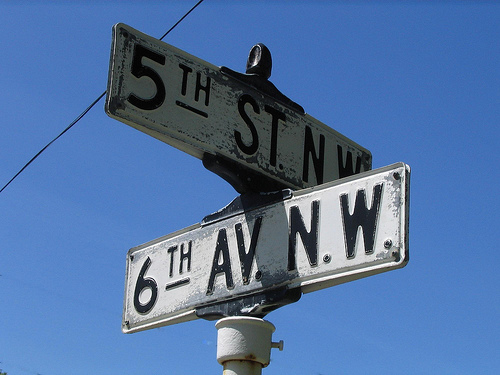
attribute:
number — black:
[128, 42, 166, 111]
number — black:
[133, 256, 157, 315]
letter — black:
[336, 182, 384, 260]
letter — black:
[284, 200, 321, 272]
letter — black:
[233, 215, 263, 285]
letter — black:
[205, 228, 236, 297]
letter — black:
[178, 240, 193, 275]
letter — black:
[166, 244, 177, 277]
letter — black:
[178, 62, 193, 96]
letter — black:
[194, 71, 211, 106]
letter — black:
[232, 92, 260, 155]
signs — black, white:
[105, 21, 411, 335]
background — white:
[103, 23, 372, 190]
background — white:
[122, 161, 410, 335]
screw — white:
[272, 340, 284, 352]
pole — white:
[214, 316, 276, 375]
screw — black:
[246, 42, 271, 81]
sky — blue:
[1, 1, 499, 375]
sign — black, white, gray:
[121, 161, 411, 335]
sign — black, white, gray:
[103, 21, 373, 188]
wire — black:
[0, 1, 205, 195]